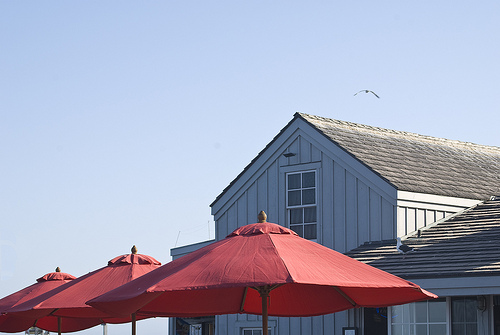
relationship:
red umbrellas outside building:
[1, 265, 89, 334] [164, 110, 499, 333]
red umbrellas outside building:
[6, 244, 180, 335] [164, 110, 499, 333]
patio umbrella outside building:
[87, 212, 440, 335] [164, 110, 499, 333]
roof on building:
[296, 110, 496, 203] [164, 110, 499, 333]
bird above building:
[349, 86, 379, 100] [164, 110, 499, 333]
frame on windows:
[278, 159, 326, 248] [282, 169, 318, 239]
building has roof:
[219, 128, 479, 328] [150, 84, 430, 261]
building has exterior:
[208, 112, 500, 335] [162, 84, 496, 220]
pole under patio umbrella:
[257, 282, 271, 335] [87, 212, 440, 335]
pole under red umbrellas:
[129, 312, 136, 334] [6, 244, 180, 335]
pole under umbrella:
[55, 313, 66, 334] [1, 263, 73, 333]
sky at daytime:
[1, 4, 498, 281] [6, 26, 483, 263]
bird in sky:
[349, 86, 379, 100] [0, 5, 499, 334]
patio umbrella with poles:
[87, 212, 440, 335] [39, 309, 174, 331]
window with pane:
[280, 170, 317, 243] [288, 177, 297, 189]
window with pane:
[280, 170, 317, 243] [302, 175, 314, 187]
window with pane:
[280, 170, 317, 243] [289, 193, 300, 203]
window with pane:
[280, 170, 317, 243] [305, 194, 315, 206]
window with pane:
[280, 170, 317, 243] [305, 212, 312, 220]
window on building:
[360, 303, 393, 333] [208, 112, 500, 335]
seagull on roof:
[394, 237, 415, 267] [405, 210, 489, 275]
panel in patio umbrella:
[82, 235, 234, 305] [144, 212, 422, 317]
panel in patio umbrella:
[145, 235, 295, 294] [144, 212, 422, 317]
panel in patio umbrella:
[264, 232, 418, 289] [144, 212, 422, 317]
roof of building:
[296, 110, 500, 202] [208, 112, 500, 335]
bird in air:
[349, 86, 379, 100] [3, 3, 498, 332]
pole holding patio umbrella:
[257, 282, 272, 332] [87, 212, 440, 335]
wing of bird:
[370, 87, 383, 102] [350, 87, 380, 100]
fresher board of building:
[396, 186, 463, 213] [208, 112, 500, 335]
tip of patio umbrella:
[257, 207, 270, 222] [87, 212, 440, 335]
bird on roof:
[349, 86, 379, 100] [325, 144, 497, 206]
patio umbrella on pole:
[87, 212, 440, 335] [257, 291, 272, 331]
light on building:
[282, 147, 297, 160] [164, 110, 499, 333]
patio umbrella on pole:
[87, 212, 440, 335] [245, 283, 280, 333]